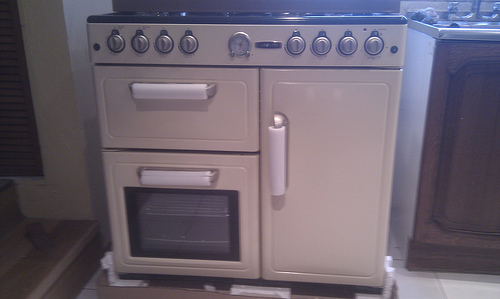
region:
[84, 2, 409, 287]
A stove and oven.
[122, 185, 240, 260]
A glass oven door.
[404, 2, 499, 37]
A silver kitchen sink.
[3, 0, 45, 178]
Part of window shutters.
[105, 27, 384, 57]
Knobs on a stove.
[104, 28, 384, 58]
Nine knobs on a stove.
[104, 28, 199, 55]
four knobs on a stove.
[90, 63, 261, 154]
A brown oven door.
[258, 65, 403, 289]
A long oven door.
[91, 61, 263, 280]
Two doors on a stove.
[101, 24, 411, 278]
this is a microwave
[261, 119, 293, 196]
this is the handle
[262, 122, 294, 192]
the handle is white in color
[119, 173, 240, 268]
the microwave is closed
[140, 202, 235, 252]
this is the screen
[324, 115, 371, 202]
the microwave is white in color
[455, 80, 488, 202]
this is a cup board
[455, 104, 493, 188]
the cup board is wooden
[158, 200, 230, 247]
the screen is clear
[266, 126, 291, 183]
the holder is rubber like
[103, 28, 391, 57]
Dials on a stove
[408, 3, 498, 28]
Part of a sink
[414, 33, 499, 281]
Part of a cabinet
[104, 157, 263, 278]
Door of an oven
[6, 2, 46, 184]
Part of an open door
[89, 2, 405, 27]
Burners of a stove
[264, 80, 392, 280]
Unknown door on a stove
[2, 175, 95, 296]
Steps between the room shown and another room.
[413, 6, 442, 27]
Sponge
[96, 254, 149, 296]
Packing foam from the box that held the stove.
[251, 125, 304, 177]
part of a handle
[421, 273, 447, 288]
part of a floor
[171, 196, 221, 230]
part of a glass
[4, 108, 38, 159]
part of a window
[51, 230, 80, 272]
part of a window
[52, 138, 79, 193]
part of a window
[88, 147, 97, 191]
part of an edge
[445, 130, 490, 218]
part of a board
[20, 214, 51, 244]
part of a floor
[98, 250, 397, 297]
The styrofoam at the bottom of the oven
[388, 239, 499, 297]
The white tile on the right of the oven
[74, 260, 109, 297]
The white tile on the left of the oven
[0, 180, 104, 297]
The wood stairs next to the stove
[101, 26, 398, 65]
The dials on the stove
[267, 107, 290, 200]
The handle on the long rectangle portion of the oven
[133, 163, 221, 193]
The handle on the portion of oven with glass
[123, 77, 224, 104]
The handle closest to the top of the oven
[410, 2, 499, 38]
The sink next to the stove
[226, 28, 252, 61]
The temp gauge on the stove